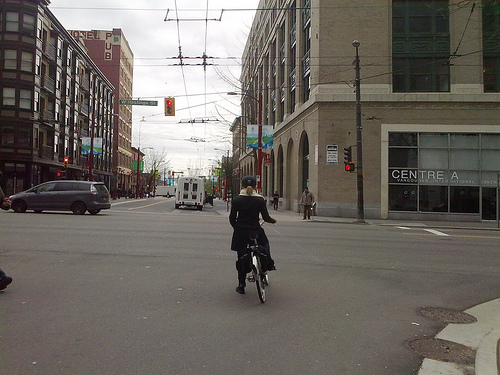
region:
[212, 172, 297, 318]
the woman riding a bike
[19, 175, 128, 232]
a grey car passing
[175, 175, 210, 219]
the back of a bus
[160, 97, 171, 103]
a red light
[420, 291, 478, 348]
a manhole cover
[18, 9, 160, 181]
a row of buildings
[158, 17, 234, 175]
a whole bunch of wires and cables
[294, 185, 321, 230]
a man on the corner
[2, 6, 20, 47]
a window on the building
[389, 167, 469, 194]
a white sign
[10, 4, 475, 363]
a city street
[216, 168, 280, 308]
woman on bicycle seen from behind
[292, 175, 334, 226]
man standing on curb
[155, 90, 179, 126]
a traffic light with the red light lit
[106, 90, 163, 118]
a street sign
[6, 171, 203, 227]
grey vehicle crossing the street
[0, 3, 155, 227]
vehicles closely packed together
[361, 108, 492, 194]
white text across windows of building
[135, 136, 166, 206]
tree beside the road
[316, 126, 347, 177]
sign on wall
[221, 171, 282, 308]
a woman on a bicycle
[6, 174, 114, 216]
a grey minivan in intersection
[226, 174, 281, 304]
a woman wearing a black winter coat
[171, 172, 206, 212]
a white van with back doors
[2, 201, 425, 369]
a city street intersection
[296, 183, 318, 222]
a pedestrian waiting to cross road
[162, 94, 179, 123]
an electric traffic signal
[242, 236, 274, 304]
a chrome bicycle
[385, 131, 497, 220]
a store glass front window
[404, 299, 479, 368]
two street manhole covers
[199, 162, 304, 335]
woman wearing a black safety helmet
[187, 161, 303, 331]
woman riding a nice clean bicycle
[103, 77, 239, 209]
traffic light with the red light on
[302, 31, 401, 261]
power pole with a traffic light light on red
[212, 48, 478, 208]
large brick building with several windown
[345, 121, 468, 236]
large front window with the letter c on it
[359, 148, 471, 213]
large front window with the letter e on it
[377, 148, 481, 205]
large front window with the letter n on it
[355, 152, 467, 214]
large front window with the letter t on it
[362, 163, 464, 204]
large front window with the letter r on it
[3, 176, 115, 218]
AN SUV ON THE LEFT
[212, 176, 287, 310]
A GIRL RIDING A BIKE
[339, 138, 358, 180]
A RED TRAFFIC LIGHT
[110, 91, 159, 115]
A GREEN STREET SIGN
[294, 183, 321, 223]
A MAN IN THE DISTANCE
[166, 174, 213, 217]
A WHITE VAN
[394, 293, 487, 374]
TWO MANHOLE COVERS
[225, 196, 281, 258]
A BLACK COAT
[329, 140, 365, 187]
A TRAFFIC LIGHT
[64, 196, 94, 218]
REAR CAR TIRE